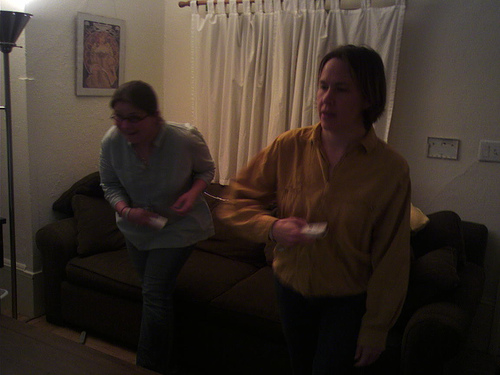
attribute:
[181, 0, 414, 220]
curtain — white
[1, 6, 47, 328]
lamp — tall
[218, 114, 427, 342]
shirt — yellow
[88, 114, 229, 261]
shirt — blue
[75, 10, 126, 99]
matting — white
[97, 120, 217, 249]
shirt — gray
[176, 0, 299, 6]
rod — wood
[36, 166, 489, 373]
cushion couch — brown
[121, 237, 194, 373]
jeans — blue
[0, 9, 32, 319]
floor lamp — black, metal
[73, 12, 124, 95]
picture — framed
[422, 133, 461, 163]
plaque — small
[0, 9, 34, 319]
lamp — tall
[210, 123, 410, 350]
shirt — tan, long sleeve, brown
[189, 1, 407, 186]
curtain — long white, white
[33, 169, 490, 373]
couch — brown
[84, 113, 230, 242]
shirt — long , sleeve 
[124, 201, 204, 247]
controller — white 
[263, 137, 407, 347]
shirt — Gold 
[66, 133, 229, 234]
shirt — gray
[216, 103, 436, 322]
shirt — yellow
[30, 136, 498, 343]
couch — brown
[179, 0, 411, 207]
curtains — white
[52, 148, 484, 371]
couch — brown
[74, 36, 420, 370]
couple — playing wii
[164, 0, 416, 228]
curtains — white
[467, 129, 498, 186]
light switch — white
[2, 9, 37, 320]
lamp — tall, floor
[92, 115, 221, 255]
shirt — blue